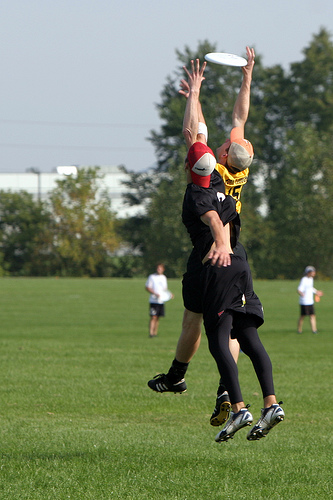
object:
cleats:
[211, 402, 231, 425]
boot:
[214, 402, 253, 444]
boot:
[246, 401, 285, 442]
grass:
[4, 282, 332, 499]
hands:
[183, 59, 208, 86]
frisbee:
[204, 51, 248, 67]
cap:
[187, 141, 217, 188]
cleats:
[147, 387, 186, 395]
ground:
[3, 285, 332, 498]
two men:
[149, 45, 287, 447]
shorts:
[201, 253, 263, 329]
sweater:
[181, 168, 240, 249]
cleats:
[247, 415, 284, 442]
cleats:
[216, 420, 252, 444]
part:
[188, 211, 196, 221]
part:
[132, 457, 141, 466]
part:
[148, 474, 157, 487]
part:
[58, 379, 91, 405]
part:
[146, 425, 170, 449]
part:
[115, 416, 144, 449]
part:
[115, 427, 129, 447]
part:
[138, 456, 161, 477]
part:
[141, 446, 150, 458]